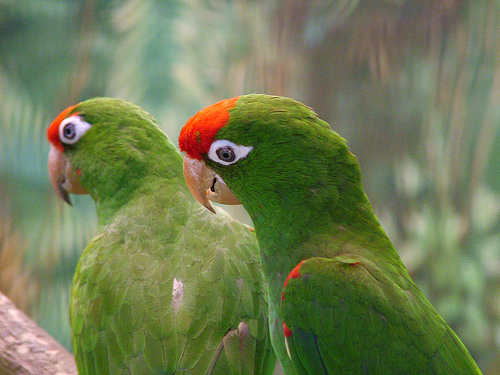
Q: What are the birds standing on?
A: Branch.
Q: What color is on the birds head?
A: Orange.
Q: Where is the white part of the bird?
A: Around the eye.